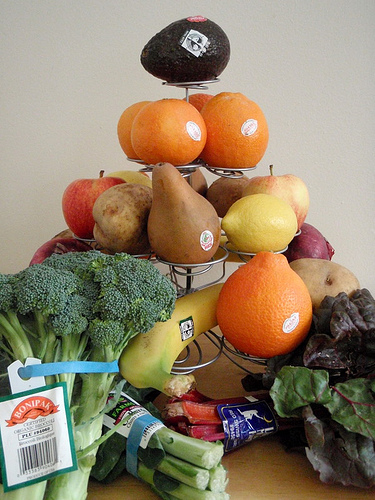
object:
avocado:
[140, 15, 232, 81]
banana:
[121, 281, 227, 398]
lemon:
[220, 192, 297, 251]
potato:
[93, 180, 153, 253]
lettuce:
[262, 288, 374, 492]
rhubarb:
[162, 389, 288, 453]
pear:
[148, 161, 222, 265]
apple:
[62, 168, 128, 240]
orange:
[129, 98, 209, 165]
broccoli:
[0, 249, 177, 500]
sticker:
[181, 27, 209, 56]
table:
[75, 304, 373, 500]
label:
[0, 380, 78, 491]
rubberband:
[17, 358, 122, 376]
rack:
[68, 77, 304, 379]